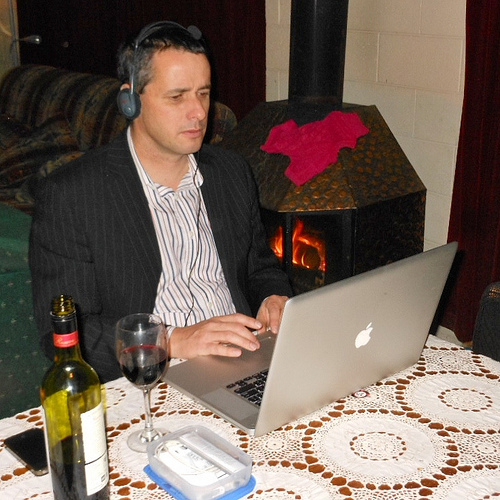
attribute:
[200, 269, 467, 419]
macbook — silver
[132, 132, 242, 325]
shirt — striped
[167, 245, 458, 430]
laptop computer — gray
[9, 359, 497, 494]
tablecloth — white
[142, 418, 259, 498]
container — small, clear, plastic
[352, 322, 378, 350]
apple logo — white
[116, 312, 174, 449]
wine — red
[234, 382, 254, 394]
key — black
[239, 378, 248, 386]
key — black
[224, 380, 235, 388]
key — black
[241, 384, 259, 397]
key — black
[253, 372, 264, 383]
key — black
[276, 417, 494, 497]
tablecloth — white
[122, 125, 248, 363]
shirt — striped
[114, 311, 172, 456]
glass — tall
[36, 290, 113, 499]
bottle — large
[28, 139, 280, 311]
suit jacket — striped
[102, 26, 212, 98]
hair — black, short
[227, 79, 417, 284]
fireplace — metal, indoor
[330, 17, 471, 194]
wall — brick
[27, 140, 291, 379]
outfit — light and dark